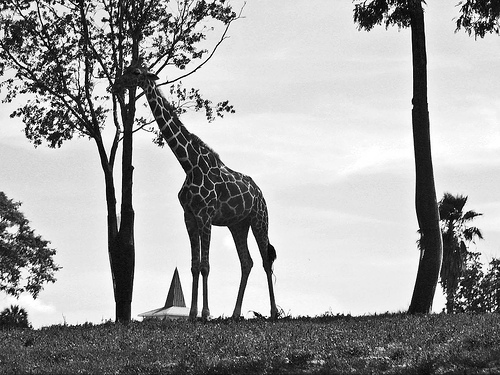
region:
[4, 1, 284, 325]
giraffe grazing from tree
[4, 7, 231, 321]
tree giraffe is grazing from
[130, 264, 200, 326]
building on the horizon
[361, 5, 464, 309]
tree on the right side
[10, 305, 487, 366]
grassy area giraffe is standing in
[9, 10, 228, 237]
branches of tree giraffe is grazing from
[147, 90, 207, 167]
long neck of the giraffe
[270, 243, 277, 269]
black tail of the giraffe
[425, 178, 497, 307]
trees in the background on right side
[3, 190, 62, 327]
trees in the background on the left side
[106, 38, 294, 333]
giraffe eating leaves from a tree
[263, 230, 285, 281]
black tuft of a giraffe tail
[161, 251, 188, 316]
point on a roof top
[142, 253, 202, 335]
roof top over the horizon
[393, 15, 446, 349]
long skinny tree trunk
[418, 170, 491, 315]
palm tree in the distance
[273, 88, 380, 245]
cloudy sky with wispy clouds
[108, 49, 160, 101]
giraffe eating leaves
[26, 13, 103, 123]
leaves in tree branches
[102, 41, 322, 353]
solo giraffe on a hill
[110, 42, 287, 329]
giraffe eating off of a tree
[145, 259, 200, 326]
pointy roof in the distance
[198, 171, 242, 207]
spots on the side of a giraffe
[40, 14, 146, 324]
tall tree with leaves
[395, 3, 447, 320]
tall dark tree trunk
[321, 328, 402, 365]
short mowed grass in a field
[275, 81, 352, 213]
overcast grey sky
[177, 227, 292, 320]
four legs of a giraffe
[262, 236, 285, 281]
tuft on the tail of a giraffe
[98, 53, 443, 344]
a giraffe in a zoo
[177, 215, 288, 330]
the legs of a giraffe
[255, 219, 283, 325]
the leg of a giraffe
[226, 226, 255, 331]
the leg of a giraffe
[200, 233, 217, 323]
the leg of a giraffe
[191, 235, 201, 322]
the leg of a giraffe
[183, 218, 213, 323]
the front legs of a giraffe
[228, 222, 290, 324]
the back legs of a giraffe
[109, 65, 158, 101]
the head of a giraffe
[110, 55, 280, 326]
a giraffe eating leaves off the tree branch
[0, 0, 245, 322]
a green leafy tree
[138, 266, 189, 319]
a steeple on a building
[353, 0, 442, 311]
a tall palm tree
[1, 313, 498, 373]
a grass field in the yard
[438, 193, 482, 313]
a small palm tree in the background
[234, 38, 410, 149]
streak clouds in the sky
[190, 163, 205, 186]
the giraffe's brown spots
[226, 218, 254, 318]
the giraffes powerful hind leg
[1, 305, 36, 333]
a small palm bush in the background